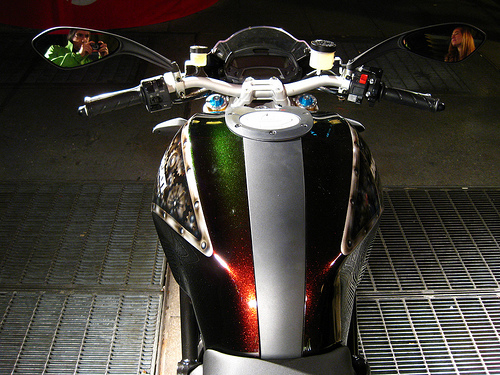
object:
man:
[44, 29, 109, 67]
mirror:
[31, 25, 488, 70]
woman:
[446, 28, 475, 64]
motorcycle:
[30, 23, 486, 375]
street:
[0, 1, 499, 373]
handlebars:
[76, 65, 444, 118]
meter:
[212, 30, 312, 83]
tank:
[225, 107, 315, 360]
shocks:
[179, 283, 360, 370]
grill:
[2, 179, 499, 372]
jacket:
[44, 41, 102, 67]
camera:
[90, 43, 102, 50]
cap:
[225, 106, 315, 142]